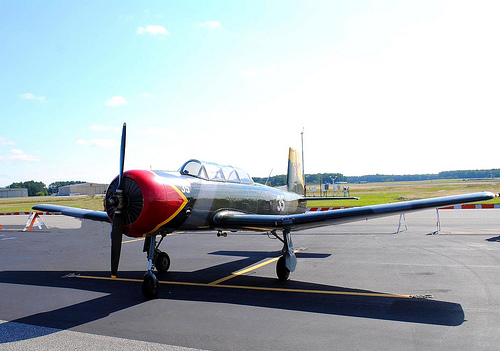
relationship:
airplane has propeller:
[37, 93, 483, 295] [93, 117, 147, 283]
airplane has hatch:
[37, 93, 483, 295] [173, 150, 258, 188]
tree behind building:
[8, 181, 83, 192] [57, 182, 110, 197]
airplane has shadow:
[37, 93, 483, 295] [2, 229, 477, 347]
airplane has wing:
[37, 93, 483, 295] [206, 177, 494, 234]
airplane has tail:
[37, 93, 483, 295] [275, 149, 359, 206]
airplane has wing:
[37, 93, 483, 295] [27, 196, 111, 232]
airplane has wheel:
[37, 93, 483, 295] [267, 256, 300, 284]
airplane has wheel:
[37, 93, 483, 295] [140, 270, 158, 298]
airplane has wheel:
[37, 93, 483, 295] [152, 249, 173, 274]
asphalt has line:
[6, 205, 500, 350] [69, 264, 410, 310]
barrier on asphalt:
[1, 211, 61, 232] [6, 205, 500, 350]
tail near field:
[275, 149, 359, 206] [297, 179, 498, 212]